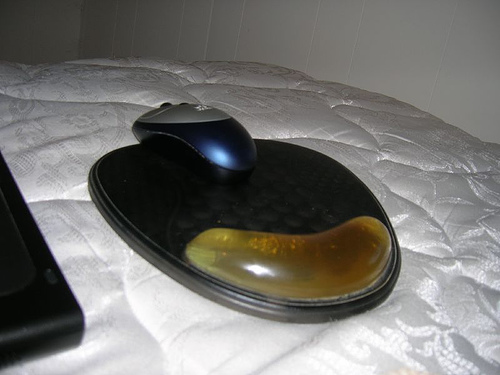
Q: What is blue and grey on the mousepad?
A: A mouse.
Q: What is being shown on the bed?
A: A mouse and mousepad.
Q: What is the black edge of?
A: A laptop.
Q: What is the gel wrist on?
A: A mouse pad.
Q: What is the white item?
A: A mattress.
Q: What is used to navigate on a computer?
A: A mouse.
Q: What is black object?
A: Laptop.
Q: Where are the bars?
A: On wall.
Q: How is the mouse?
A: Wireless.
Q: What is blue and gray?
A: Mouse.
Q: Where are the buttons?
A: Mouse.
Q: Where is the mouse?
A: Mouse pad.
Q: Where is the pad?
A: On blanket.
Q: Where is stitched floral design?
A: On white blanket.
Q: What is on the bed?
A: White comforter.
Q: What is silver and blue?
A: A mouse.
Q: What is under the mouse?
A: Mousepad.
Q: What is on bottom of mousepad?
A: Gel filling.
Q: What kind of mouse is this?
A: Wireless.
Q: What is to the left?
A: Computer.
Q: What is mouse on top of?
A: A bed.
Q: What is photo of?
A: Wireless mouse.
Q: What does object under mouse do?
A: Helps roll mouse.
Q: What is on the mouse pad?
A: Mouse.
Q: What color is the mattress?
A: White.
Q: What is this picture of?
A: Mouse, and mouse pad.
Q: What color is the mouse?
A: Black.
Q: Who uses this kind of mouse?
A: A human.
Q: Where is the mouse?
A: On the mouse pad.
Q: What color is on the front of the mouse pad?
A: Yellowish Orange.